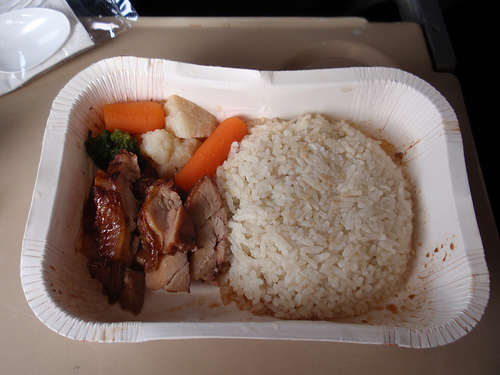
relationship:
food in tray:
[75, 93, 421, 326] [261, 76, 343, 108]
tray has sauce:
[261, 76, 343, 108] [395, 138, 409, 166]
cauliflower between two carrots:
[165, 104, 199, 145] [108, 100, 243, 150]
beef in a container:
[101, 177, 177, 256] [149, 62, 236, 93]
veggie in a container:
[102, 134, 153, 153] [149, 62, 236, 93]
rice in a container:
[243, 128, 402, 303] [149, 62, 236, 93]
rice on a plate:
[243, 128, 402, 303] [329, 76, 375, 97]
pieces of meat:
[127, 183, 157, 236] [134, 194, 205, 264]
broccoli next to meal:
[88, 131, 136, 155] [118, 83, 384, 213]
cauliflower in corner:
[165, 104, 199, 145] [152, 90, 179, 101]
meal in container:
[118, 83, 384, 213] [149, 62, 236, 93]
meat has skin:
[134, 194, 205, 264] [107, 177, 118, 207]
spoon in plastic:
[8, 10, 72, 56] [81, 28, 104, 54]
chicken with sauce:
[117, 157, 139, 174] [395, 138, 409, 166]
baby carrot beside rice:
[103, 102, 165, 135] [243, 128, 402, 303]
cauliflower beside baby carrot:
[165, 104, 199, 145] [113, 108, 157, 126]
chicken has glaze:
[117, 157, 139, 174] [102, 163, 141, 180]